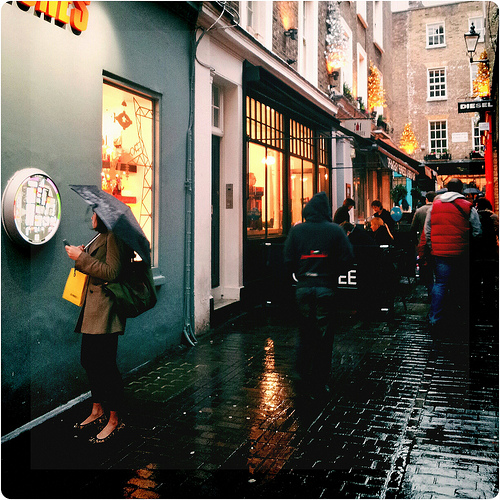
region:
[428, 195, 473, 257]
a red vest on a man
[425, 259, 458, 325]
blue jeans on a man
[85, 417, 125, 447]
a black shoe on a woman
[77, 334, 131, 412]
black pants on a woman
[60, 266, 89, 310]
a yellow bag on a woman's wrist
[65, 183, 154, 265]
an umbrella carried by a woman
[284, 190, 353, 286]
a black jacket on a man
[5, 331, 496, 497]
a wet brick walkway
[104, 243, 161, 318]
a green bag on a woman's shoulder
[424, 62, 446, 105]
a window in a building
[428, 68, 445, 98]
a window on the building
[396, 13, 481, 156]
a brown building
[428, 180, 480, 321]
a man with a red ves ton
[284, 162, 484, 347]
people walking in between buildings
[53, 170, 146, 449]
a lady carrying a yellow bag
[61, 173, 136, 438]
a lady carrying an umbrella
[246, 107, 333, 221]
large windows on the building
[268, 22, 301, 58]
bricks on the building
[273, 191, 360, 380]
a man with his hood on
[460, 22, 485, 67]
a light attached to the building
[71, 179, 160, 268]
thats a black umbrella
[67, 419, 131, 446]
those are her shoes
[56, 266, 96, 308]
thats a yellow bag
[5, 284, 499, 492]
thats the black sidewalk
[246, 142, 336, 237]
these are picture windows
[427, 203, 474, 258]
thats a red jacket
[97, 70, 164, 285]
thats a large window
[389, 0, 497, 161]
this is a building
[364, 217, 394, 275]
thats a woman sitting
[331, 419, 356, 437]
brick on the sidewalk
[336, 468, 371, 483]
brick on the sidewalk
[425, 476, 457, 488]
brick on the sidewalk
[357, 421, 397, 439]
brick on the sidewalk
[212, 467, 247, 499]
brick on the sidewalk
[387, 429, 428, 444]
brick on the sidewalk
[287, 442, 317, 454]
brick on the sidewalk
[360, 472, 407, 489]
brick on the sidewalk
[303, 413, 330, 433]
brick on the sidewalk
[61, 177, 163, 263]
Woman holding a black umbrella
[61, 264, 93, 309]
Yellow bag with black letters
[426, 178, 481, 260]
Man wearing red short sleeved jacket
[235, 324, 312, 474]
Light reflection on wet brick street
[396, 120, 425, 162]
Tree with clear lights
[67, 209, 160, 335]
Woman with black bag hanging on her shoulder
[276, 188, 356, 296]
Person wearing black jacket with a hood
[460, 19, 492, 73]
Black framed wall mounted lamp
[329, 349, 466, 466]
Shiny brick street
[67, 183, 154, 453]
Woman wearing short black pants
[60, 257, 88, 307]
A woman carrying a yellow bag.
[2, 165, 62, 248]
A map on the building.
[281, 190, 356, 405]
A person wearing a hoodie.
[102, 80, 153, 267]
A window on the building.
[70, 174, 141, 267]
a woman holding a umbrella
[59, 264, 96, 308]
a woman holding a yellow bag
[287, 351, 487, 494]
a wet brick sidewalk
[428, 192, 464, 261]
a person wearing a red vest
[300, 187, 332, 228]
a person with a hood on their head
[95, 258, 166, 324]
a woman holding a green bag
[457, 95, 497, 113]
a black sign with white letters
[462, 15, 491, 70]
a black light fixture attached to a building